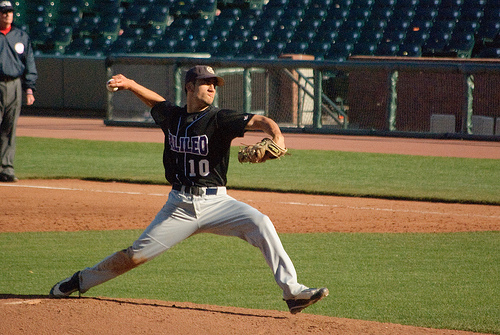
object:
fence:
[25, 55, 500, 141]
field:
[1, 113, 500, 334]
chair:
[277, 38, 295, 53]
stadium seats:
[395, 42, 424, 57]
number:
[186, 158, 196, 179]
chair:
[333, 41, 354, 57]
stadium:
[0, 0, 499, 335]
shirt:
[148, 99, 254, 186]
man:
[51, 64, 330, 314]